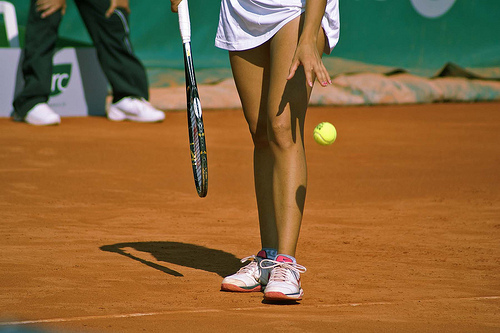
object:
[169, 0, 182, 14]
finger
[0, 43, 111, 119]
wheeled tote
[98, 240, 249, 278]
shadow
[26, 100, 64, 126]
sneakers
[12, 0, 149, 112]
pants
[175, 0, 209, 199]
racket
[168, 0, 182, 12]
hand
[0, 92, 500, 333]
court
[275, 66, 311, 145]
shadow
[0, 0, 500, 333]
photo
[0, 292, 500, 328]
markings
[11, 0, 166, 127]
man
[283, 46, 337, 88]
hands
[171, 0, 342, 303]
player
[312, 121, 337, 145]
ball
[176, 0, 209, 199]
tennis racket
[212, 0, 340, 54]
skirt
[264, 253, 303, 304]
tennis shoe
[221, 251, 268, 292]
tennis shoe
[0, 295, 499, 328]
white line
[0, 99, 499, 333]
dirt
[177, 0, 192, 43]
handle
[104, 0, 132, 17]
hand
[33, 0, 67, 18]
hand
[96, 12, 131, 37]
knee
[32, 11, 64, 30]
knee